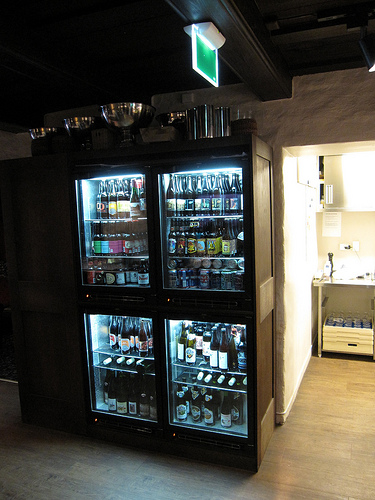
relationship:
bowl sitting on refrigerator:
[29, 124, 59, 137] [71, 131, 271, 473]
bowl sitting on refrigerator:
[61, 115, 96, 131] [71, 131, 271, 473]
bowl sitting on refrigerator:
[97, 100, 154, 130] [71, 131, 271, 473]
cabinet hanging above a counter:
[304, 151, 336, 201] [313, 263, 374, 290]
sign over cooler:
[184, 23, 226, 89] [74, 131, 277, 470]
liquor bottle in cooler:
[203, 213, 220, 258] [53, 156, 277, 477]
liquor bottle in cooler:
[218, 216, 233, 255] [53, 156, 277, 477]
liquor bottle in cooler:
[166, 216, 176, 254] [53, 156, 277, 477]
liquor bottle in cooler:
[211, 170, 223, 214] [53, 156, 277, 477]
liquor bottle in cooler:
[235, 327, 248, 373] [53, 156, 277, 477]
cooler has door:
[40, 134, 277, 435] [69, 170, 154, 288]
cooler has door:
[40, 134, 277, 435] [157, 166, 248, 294]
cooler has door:
[40, 134, 277, 435] [84, 311, 156, 422]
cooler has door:
[40, 134, 277, 435] [163, 311, 248, 439]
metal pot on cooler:
[186, 101, 231, 138] [74, 131, 277, 470]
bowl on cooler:
[98, 102, 156, 147] [74, 131, 277, 470]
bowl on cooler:
[64, 116, 95, 136] [74, 131, 277, 470]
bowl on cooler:
[29, 127, 58, 140] [74, 131, 277, 470]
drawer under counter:
[321, 315, 372, 357] [309, 256, 373, 333]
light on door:
[85, 292, 90, 297] [79, 310, 160, 428]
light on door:
[163, 296, 175, 305] [161, 316, 254, 451]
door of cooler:
[161, 316, 254, 451] [53, 156, 277, 477]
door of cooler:
[79, 310, 160, 428] [53, 156, 277, 477]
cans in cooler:
[165, 259, 242, 289] [74, 131, 277, 470]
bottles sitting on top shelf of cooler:
[91, 174, 239, 212] [67, 132, 275, 472]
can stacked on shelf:
[235, 275, 240, 288] [166, 289, 241, 294]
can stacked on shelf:
[220, 272, 229, 287] [166, 289, 241, 294]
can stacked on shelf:
[199, 269, 207, 289] [166, 289, 241, 294]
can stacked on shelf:
[207, 270, 217, 287] [166, 289, 241, 294]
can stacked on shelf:
[181, 266, 189, 286] [166, 289, 241, 294]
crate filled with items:
[321, 314, 373, 356] [323, 315, 371, 326]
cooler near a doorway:
[67, 132, 275, 472] [272, 140, 373, 435]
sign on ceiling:
[191, 23, 219, 89] [121, 3, 320, 105]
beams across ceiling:
[166, 3, 298, 103] [1, 0, 371, 116]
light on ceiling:
[183, 21, 228, 83] [126, 10, 310, 144]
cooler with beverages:
[67, 132, 275, 472] [157, 166, 244, 224]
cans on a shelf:
[170, 258, 244, 292] [37, 128, 330, 473]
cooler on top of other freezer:
[67, 132, 275, 472] [81, 310, 249, 438]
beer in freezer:
[93, 183, 154, 217] [55, 115, 286, 475]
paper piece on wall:
[276, 63, 367, 198] [265, 65, 371, 150]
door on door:
[251, 133, 290, 427] [251, 135, 276, 474]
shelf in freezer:
[172, 355, 245, 377] [163, 318, 248, 439]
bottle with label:
[167, 151, 223, 205] [150, 197, 216, 210]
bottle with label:
[217, 326, 230, 372] [212, 345, 229, 374]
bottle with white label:
[203, 322, 213, 364] [208, 347, 219, 367]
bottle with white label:
[216, 325, 231, 371] [216, 351, 229, 369]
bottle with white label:
[185, 332, 196, 364] [175, 341, 184, 360]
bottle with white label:
[218, 387, 231, 429] [106, 330, 117, 345]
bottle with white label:
[116, 316, 134, 355] [209, 344, 219, 368]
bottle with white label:
[189, 384, 202, 423] [189, 405, 199, 421]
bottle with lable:
[174, 380, 188, 420] [175, 403, 186, 419]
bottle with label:
[217, 324, 235, 371] [219, 349, 229, 369]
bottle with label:
[199, 386, 217, 427] [202, 406, 214, 425]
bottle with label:
[103, 369, 119, 413] [105, 397, 118, 411]